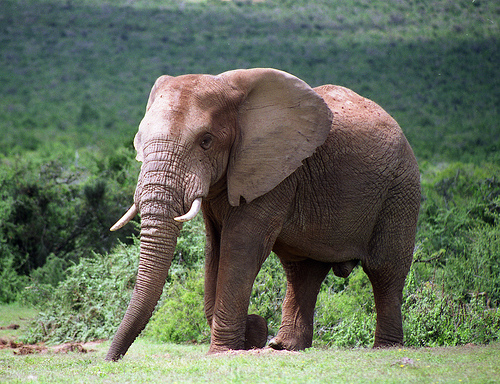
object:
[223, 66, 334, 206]
ear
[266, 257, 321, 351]
leg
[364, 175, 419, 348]
leg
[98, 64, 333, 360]
head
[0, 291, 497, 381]
field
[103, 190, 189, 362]
elephant trunk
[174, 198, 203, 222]
elephant tusk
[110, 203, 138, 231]
elephant tusk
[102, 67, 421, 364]
elephant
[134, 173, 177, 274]
wrinkles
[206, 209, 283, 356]
leg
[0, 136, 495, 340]
trees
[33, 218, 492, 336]
brush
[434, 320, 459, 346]
leaf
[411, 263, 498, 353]
stem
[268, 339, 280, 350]
toenail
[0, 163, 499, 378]
grass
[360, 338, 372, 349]
leaf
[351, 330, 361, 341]
stem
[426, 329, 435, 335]
leaf